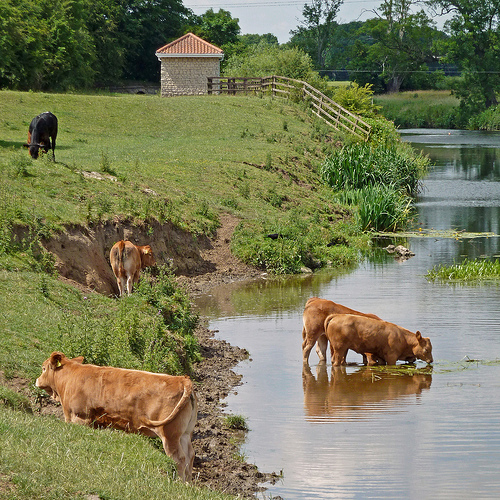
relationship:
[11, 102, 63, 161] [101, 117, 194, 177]
animal on grass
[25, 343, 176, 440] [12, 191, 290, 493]
cow standing on land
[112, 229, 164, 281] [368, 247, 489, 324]
cow looking towards water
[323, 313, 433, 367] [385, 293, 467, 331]
cow drinking stream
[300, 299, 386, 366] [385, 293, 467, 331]
cow drinking stream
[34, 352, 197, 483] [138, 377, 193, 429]
cow flicking tail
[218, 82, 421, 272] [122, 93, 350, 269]
edge of a hill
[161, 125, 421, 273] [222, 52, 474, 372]
edge of a shore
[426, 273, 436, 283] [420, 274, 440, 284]
part of bush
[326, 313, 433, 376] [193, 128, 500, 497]
cow standing in stream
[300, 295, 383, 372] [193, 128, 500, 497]
cow standing in stream